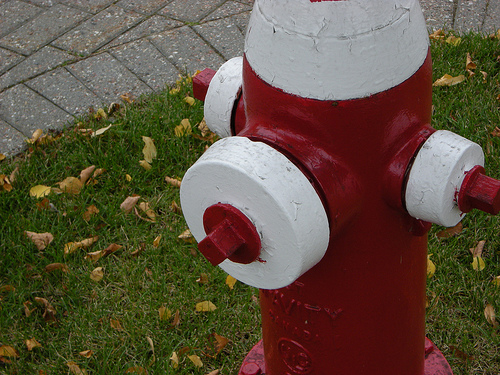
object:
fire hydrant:
[178, 1, 499, 374]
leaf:
[29, 184, 51, 199]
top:
[244, 0, 429, 100]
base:
[241, 333, 454, 374]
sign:
[260, 284, 342, 373]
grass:
[2, 34, 497, 374]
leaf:
[26, 231, 54, 251]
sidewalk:
[0, 0, 500, 157]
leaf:
[196, 300, 217, 311]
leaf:
[433, 73, 468, 87]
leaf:
[120, 197, 137, 213]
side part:
[405, 129, 499, 227]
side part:
[192, 57, 243, 138]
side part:
[180, 136, 332, 290]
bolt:
[197, 205, 261, 268]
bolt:
[192, 65, 217, 103]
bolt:
[458, 164, 500, 217]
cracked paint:
[264, 11, 419, 47]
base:
[405, 130, 485, 230]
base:
[203, 57, 244, 136]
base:
[177, 134, 327, 290]